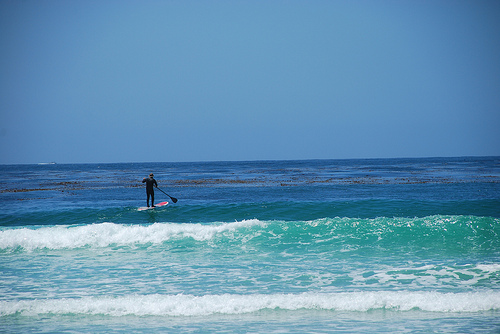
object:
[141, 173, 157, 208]
man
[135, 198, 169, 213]
board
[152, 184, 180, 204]
paddle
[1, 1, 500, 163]
sky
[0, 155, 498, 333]
ocean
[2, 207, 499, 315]
wave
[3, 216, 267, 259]
sea foam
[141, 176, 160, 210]
wet suit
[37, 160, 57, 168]
boat